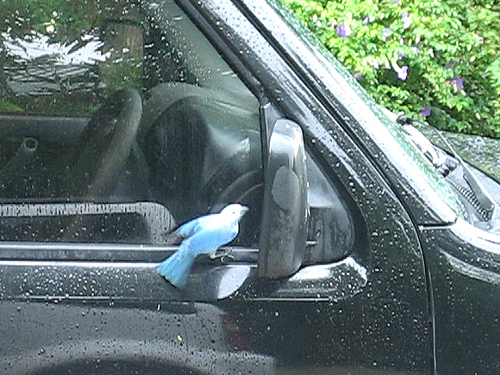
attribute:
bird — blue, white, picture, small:
[174, 199, 245, 273]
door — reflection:
[37, 276, 185, 338]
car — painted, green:
[1, 32, 462, 331]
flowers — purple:
[330, 21, 385, 48]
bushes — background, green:
[420, 3, 460, 28]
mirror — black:
[256, 114, 341, 284]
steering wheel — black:
[46, 87, 149, 206]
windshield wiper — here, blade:
[443, 134, 489, 206]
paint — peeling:
[193, 27, 237, 39]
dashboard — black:
[184, 80, 253, 120]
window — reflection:
[62, 0, 218, 62]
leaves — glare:
[8, 11, 61, 28]